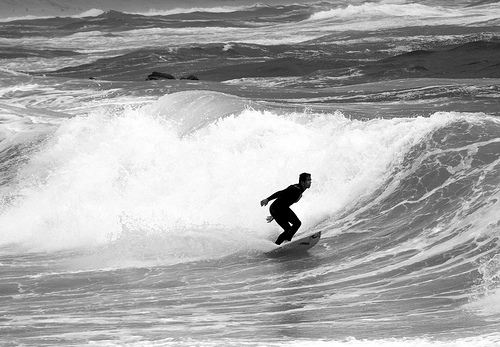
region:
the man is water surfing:
[246, 140, 340, 280]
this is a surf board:
[258, 228, 340, 270]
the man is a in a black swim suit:
[245, 134, 321, 250]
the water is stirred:
[142, 130, 242, 262]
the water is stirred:
[310, 112, 395, 204]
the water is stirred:
[39, 150, 143, 270]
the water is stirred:
[111, 100, 246, 215]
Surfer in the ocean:
[255, 165, 333, 272]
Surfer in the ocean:
[240, 150, 326, 265]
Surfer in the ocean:
[243, 158, 333, 260]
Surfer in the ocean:
[242, 161, 338, 251]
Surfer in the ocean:
[251, 153, 333, 259]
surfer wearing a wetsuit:
[267, 175, 298, 235]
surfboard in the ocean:
[266, 230, 328, 253]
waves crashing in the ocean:
[93, 84, 253, 207]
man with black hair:
[296, 168, 318, 186]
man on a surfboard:
[256, 155, 313, 238]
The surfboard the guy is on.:
[262, 229, 326, 254]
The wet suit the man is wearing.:
[272, 184, 302, 241]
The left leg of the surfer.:
[277, 213, 288, 248]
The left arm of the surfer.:
[262, 189, 290, 205]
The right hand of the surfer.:
[267, 213, 272, 220]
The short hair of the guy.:
[297, 173, 309, 179]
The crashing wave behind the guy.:
[17, 103, 378, 265]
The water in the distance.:
[12, 7, 499, 83]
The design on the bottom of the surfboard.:
[300, 232, 318, 252]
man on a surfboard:
[256, 167, 313, 243]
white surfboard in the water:
[264, 226, 329, 258]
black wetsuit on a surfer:
[265, 178, 305, 236]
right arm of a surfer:
[256, 185, 297, 200]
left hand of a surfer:
[265, 214, 275, 225]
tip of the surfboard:
[313, 228, 323, 239]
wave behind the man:
[12, 100, 456, 260]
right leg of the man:
[270, 210, 291, 245]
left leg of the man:
[286, 204, 304, 239]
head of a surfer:
[299, 169, 315, 189]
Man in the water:
[256, 150, 342, 277]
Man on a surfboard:
[254, 161, 318, 246]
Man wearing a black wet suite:
[258, 154, 319, 237]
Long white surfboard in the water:
[253, 234, 357, 274]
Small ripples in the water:
[18, 299, 83, 344]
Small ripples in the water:
[158, 274, 210, 338]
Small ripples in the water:
[218, 262, 256, 332]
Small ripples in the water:
[350, 286, 401, 338]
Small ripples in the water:
[421, 246, 479, 300]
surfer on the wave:
[250, 168, 321, 250]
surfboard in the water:
[265, 233, 317, 257]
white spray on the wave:
[21, 114, 401, 224]